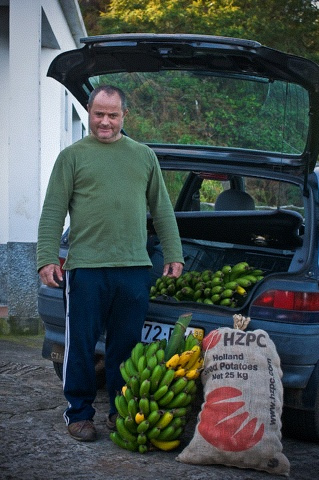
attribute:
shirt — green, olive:
[34, 136, 185, 270]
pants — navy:
[61, 265, 152, 425]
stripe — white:
[62, 270, 73, 427]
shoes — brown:
[66, 414, 119, 442]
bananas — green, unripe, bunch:
[113, 312, 206, 455]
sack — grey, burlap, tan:
[175, 314, 293, 478]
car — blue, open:
[38, 32, 319, 441]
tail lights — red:
[252, 288, 318, 325]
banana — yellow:
[153, 437, 180, 453]